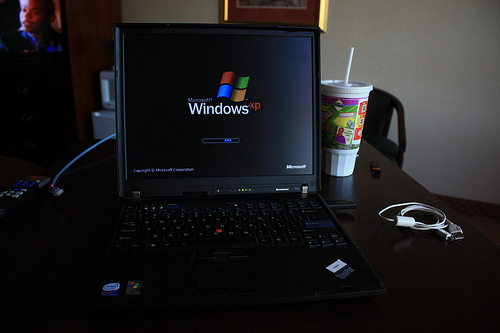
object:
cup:
[320, 44, 374, 178]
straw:
[343, 47, 356, 83]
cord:
[377, 202, 462, 244]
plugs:
[438, 229, 456, 241]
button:
[215, 229, 222, 233]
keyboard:
[104, 199, 350, 256]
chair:
[357, 87, 408, 168]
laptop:
[84, 26, 386, 302]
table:
[3, 139, 499, 330]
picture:
[240, 2, 306, 7]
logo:
[187, 70, 261, 117]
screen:
[130, 35, 311, 178]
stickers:
[100, 281, 121, 296]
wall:
[335, 1, 493, 200]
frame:
[221, 0, 330, 30]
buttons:
[28, 183, 34, 187]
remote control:
[4, 173, 51, 212]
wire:
[50, 126, 115, 183]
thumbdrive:
[370, 161, 381, 179]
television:
[4, 2, 70, 56]